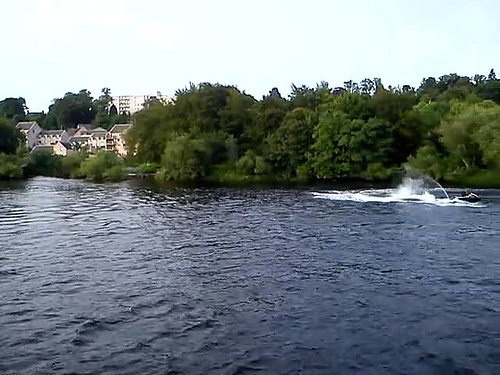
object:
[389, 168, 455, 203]
jetski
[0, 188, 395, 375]
water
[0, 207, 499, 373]
lake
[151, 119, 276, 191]
trees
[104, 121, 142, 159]
building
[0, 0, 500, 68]
sky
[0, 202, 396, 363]
ripple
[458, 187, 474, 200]
person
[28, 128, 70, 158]
buliding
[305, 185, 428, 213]
wave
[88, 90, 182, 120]
hotel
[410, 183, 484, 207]
boat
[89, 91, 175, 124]
bulidings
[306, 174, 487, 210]
foam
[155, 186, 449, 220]
stream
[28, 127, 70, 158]
houses